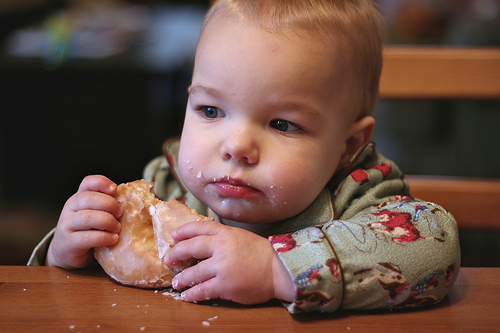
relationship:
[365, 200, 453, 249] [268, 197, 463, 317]
pattern on sleeve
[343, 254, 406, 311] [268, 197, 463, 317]
pattern on sleeve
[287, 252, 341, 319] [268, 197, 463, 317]
pattern on sleeve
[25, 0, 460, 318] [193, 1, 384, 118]
baby has hair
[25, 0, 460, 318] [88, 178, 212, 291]
baby eating donut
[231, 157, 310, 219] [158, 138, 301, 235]
icing on mouth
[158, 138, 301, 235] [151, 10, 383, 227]
mouth on face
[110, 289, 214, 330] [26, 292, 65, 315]
crumbs on table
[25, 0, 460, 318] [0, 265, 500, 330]
baby on table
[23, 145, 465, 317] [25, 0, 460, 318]
pajamas on baby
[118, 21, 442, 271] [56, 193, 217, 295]
baby with donut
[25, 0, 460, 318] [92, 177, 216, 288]
baby with donut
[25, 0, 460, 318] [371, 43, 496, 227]
baby in chair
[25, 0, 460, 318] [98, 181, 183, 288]
baby with donut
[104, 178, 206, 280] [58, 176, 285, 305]
donut in hands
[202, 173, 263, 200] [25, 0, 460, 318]
mouth on baby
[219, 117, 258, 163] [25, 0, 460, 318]
nose of baby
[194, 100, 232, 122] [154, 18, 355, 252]
eye of baby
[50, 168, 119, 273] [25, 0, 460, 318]
hand of baby